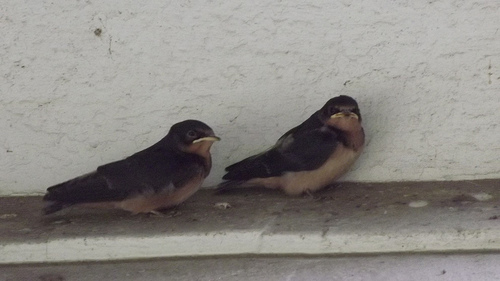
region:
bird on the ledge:
[257, 90, 359, 203]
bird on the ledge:
[59, 122, 209, 214]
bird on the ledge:
[244, 104, 406, 193]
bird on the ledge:
[65, 123, 207, 224]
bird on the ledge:
[67, 108, 231, 225]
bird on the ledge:
[230, 75, 390, 213]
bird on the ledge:
[32, 111, 224, 212]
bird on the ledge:
[232, 85, 390, 215]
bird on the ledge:
[50, 110, 239, 237]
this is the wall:
[100, 59, 142, 79]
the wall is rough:
[79, 80, 128, 102]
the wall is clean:
[42, 62, 119, 102]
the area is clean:
[254, 208, 289, 228]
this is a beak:
[199, 136, 219, 143]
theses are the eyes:
[329, 99, 360, 114]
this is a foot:
[306, 188, 327, 201]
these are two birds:
[52, 95, 385, 199]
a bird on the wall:
[33, 106, 215, 226]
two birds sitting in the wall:
[42, 64, 367, 209]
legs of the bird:
[137, 200, 197, 232]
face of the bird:
[171, 117, 234, 156]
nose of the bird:
[201, 131, 227, 145]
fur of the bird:
[273, 144, 318, 170]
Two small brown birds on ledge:
[30, 80, 404, 235]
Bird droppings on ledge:
[177, 173, 497, 229]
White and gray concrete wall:
[5, 0, 494, 280]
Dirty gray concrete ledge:
[5, 148, 496, 258]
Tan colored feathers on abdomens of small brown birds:
[94, 143, 378, 228]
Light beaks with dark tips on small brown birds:
[190, 102, 370, 152]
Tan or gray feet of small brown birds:
[133, 181, 371, 226]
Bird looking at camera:
[215, 86, 369, 194]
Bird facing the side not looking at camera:
[5, 110, 227, 228]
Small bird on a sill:
[38, 114, 223, 222]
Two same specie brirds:
[38, 89, 368, 220]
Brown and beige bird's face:
[168, 115, 224, 154]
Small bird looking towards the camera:
[318, 91, 366, 125]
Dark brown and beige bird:
[217, 94, 368, 204]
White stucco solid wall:
[187, 9, 325, 91]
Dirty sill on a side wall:
[353, 175, 498, 255]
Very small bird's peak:
[188, 130, 223, 147]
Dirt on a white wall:
[6, 48, 77, 121]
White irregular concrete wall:
[148, 10, 303, 110]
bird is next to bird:
[40, 93, 362, 221]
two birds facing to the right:
[30, 74, 392, 247]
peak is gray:
[195, 128, 225, 146]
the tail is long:
[33, 158, 116, 224]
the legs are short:
[143, 203, 175, 224]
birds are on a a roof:
[1, 11, 498, 281]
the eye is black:
[180, 122, 203, 142]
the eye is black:
[326, 103, 346, 114]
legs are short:
[296, 180, 331, 206]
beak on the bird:
[190, 128, 222, 145]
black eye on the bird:
[185, 126, 200, 141]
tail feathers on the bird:
[212, 145, 301, 196]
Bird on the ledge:
[216, 80, 373, 208]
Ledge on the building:
[1, 158, 497, 278]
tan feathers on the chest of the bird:
[282, 103, 362, 200]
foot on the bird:
[145, 203, 174, 223]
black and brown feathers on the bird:
[223, 83, 373, 205]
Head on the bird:
[310, 93, 362, 130]